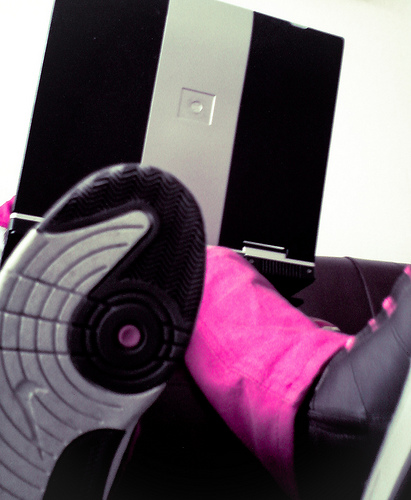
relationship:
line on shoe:
[0, 302, 72, 329] [7, 160, 196, 498]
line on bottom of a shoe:
[0, 302, 72, 329] [7, 117, 246, 465]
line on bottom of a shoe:
[6, 297, 81, 344] [7, 117, 246, 465]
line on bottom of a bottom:
[0, 302, 72, 329] [0, 162, 210, 498]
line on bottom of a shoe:
[0, 302, 72, 329] [7, 160, 196, 498]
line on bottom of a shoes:
[0, 302, 72, 329] [5, 162, 409, 496]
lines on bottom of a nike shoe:
[0, 466, 45, 498] [0, 159, 209, 498]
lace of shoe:
[343, 333, 358, 354] [299, 261, 409, 497]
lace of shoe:
[382, 294, 393, 311] [1, 159, 409, 498]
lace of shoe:
[402, 266, 409, 277] [290, 266, 410, 497]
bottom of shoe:
[2, 155, 191, 497] [7, 160, 196, 498]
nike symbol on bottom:
[8, 371, 59, 460] [2, 155, 191, 497]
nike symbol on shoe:
[8, 371, 59, 460] [7, 160, 196, 498]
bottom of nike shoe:
[0, 162, 210, 498] [2, 159, 208, 498]